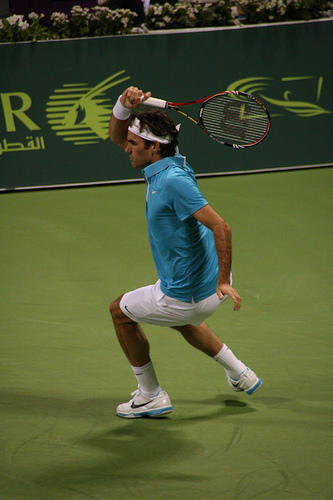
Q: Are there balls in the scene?
A: No, there are no balls.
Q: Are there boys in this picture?
A: No, there are no boys.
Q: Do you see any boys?
A: No, there are no boys.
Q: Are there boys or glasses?
A: No, there are no boys or glasses.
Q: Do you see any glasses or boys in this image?
A: No, there are no boys or glasses.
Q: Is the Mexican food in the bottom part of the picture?
A: Yes, the Mexican food is in the bottom of the image.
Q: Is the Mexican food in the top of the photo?
A: No, the Mexican food is in the bottom of the image.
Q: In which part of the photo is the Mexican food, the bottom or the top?
A: The Mexican food is in the bottom of the image.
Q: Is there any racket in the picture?
A: Yes, there is a racket.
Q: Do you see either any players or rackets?
A: Yes, there is a racket.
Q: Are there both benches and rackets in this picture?
A: No, there is a racket but no benches.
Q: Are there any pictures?
A: No, there are no pictures.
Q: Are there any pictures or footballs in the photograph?
A: No, there are no pictures or footballs.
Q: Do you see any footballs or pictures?
A: No, there are no pictures or footballs.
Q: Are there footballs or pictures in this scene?
A: No, there are no pictures or footballs.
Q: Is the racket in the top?
A: Yes, the racket is in the top of the image.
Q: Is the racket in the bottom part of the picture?
A: No, the racket is in the top of the image.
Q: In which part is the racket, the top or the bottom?
A: The racket is in the top of the image.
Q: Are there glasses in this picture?
A: No, there are no glasses.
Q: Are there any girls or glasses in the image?
A: No, there are no glasses or girls.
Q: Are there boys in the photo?
A: No, there are no boys.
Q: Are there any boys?
A: No, there are no boys.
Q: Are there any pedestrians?
A: No, there are no pedestrians.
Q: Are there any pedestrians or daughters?
A: No, there are no pedestrians or daughters.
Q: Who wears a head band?
A: The man wears a head band.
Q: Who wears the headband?
A: The man wears a head band.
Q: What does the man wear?
A: The man wears a hair band.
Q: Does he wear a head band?
A: Yes, the man wears a head band.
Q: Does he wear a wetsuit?
A: No, the man wears a head band.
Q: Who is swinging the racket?
A: The man is swinging the racket.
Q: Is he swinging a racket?
A: Yes, the man is swinging a racket.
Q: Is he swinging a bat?
A: No, the man is swinging a racket.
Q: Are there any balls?
A: No, there are no balls.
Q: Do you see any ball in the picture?
A: No, there are no balls.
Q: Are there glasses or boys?
A: No, there are no boys or glasses.